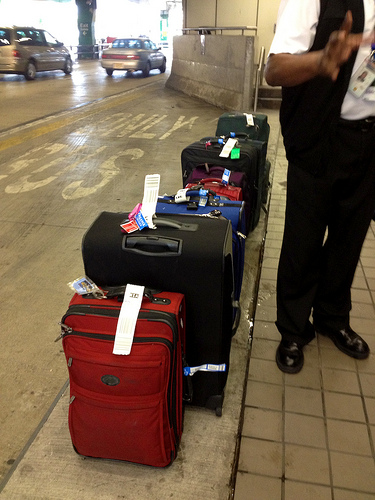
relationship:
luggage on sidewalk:
[53, 113, 272, 468] [5, 104, 373, 493]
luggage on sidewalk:
[53, 113, 272, 468] [1, 453, 236, 498]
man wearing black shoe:
[261, 0, 374, 377] [274, 326, 308, 382]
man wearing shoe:
[261, 0, 374, 377] [314, 318, 373, 362]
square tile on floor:
[285, 410, 326, 450] [234, 132, 372, 498]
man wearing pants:
[261, 0, 374, 377] [272, 141, 373, 328]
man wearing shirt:
[261, 0, 374, 377] [266, 0, 374, 122]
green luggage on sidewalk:
[217, 112, 269, 147] [122, 83, 372, 498]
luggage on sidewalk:
[53, 108, 273, 470] [5, 104, 373, 493]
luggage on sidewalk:
[53, 113, 272, 468] [0, 61, 373, 499]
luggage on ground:
[53, 113, 272, 468] [0, 59, 374, 498]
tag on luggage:
[115, 283, 137, 354] [53, 113, 272, 468]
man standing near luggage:
[261, 0, 374, 377] [53, 108, 273, 470]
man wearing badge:
[261, 0, 374, 377] [344, 61, 374, 89]